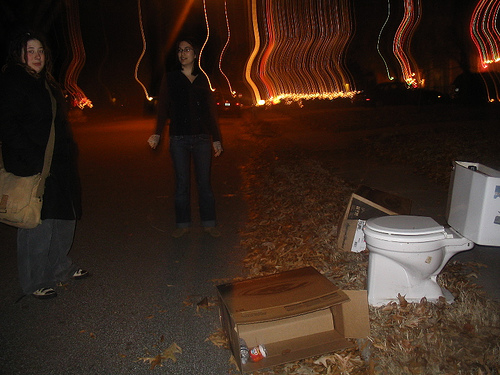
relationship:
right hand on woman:
[145, 137, 168, 150] [146, 37, 230, 239]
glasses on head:
[175, 42, 198, 56] [156, 42, 209, 82]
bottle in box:
[235, 338, 247, 370] [214, 265, 371, 373]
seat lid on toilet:
[345, 172, 450, 250] [317, 110, 497, 322]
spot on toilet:
[425, 251, 436, 279] [363, 174, 497, 311]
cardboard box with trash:
[208, 260, 373, 370] [237, 335, 265, 367]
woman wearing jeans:
[146, 30, 226, 237] [164, 146, 195, 237]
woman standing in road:
[141, 30, 235, 237] [0, 100, 411, 370]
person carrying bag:
[0, 33, 94, 300] [0, 71, 58, 230]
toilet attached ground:
[357, 155, 467, 303] [348, 135, 394, 192]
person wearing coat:
[4, 50, 81, 227] [5, 70, 86, 221]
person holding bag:
[0, 33, 94, 300] [4, 162, 45, 225]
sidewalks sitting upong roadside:
[259, 101, 454, 221] [236, 113, 368, 258]